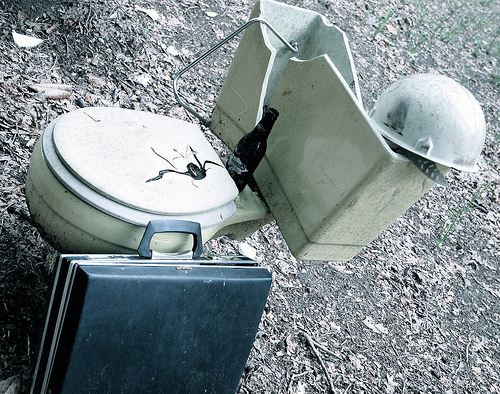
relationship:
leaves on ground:
[370, 245, 477, 349] [29, 22, 489, 389]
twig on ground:
[300, 337, 355, 393] [29, 22, 489, 389]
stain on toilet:
[143, 120, 222, 205] [5, 3, 410, 261]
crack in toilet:
[219, 39, 312, 194] [5, 3, 410, 261]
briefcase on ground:
[59, 229, 248, 390] [29, 22, 489, 389]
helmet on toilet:
[394, 69, 478, 174] [5, 3, 410, 261]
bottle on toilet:
[236, 113, 278, 193] [5, 3, 410, 261]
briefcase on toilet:
[59, 229, 248, 390] [5, 3, 410, 261]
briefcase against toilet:
[59, 229, 248, 390] [5, 3, 410, 261]